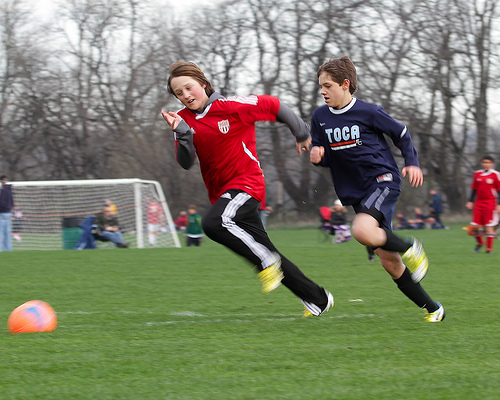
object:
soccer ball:
[8, 298, 56, 333]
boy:
[159, 60, 334, 317]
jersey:
[311, 97, 419, 231]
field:
[0, 227, 498, 399]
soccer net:
[1, 176, 182, 248]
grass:
[0, 227, 499, 396]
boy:
[308, 58, 443, 322]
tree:
[244, 1, 364, 220]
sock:
[392, 266, 439, 311]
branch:
[248, 1, 267, 82]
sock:
[477, 232, 482, 249]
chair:
[318, 207, 332, 239]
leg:
[202, 189, 275, 266]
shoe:
[260, 252, 284, 293]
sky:
[2, 2, 182, 55]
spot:
[26, 307, 40, 318]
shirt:
[175, 94, 279, 208]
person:
[187, 202, 204, 246]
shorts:
[471, 207, 497, 226]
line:
[0, 308, 374, 328]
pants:
[202, 190, 327, 316]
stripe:
[222, 192, 276, 269]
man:
[0, 176, 15, 251]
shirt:
[186, 214, 203, 236]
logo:
[323, 124, 362, 151]